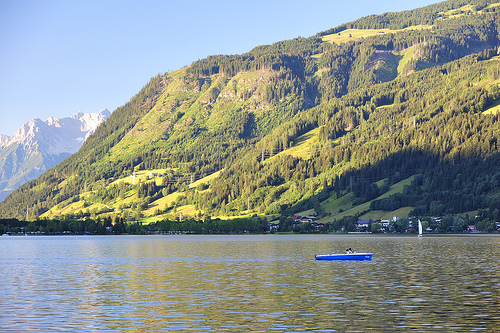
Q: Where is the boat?
A: On the sea.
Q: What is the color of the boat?
A: Blue.